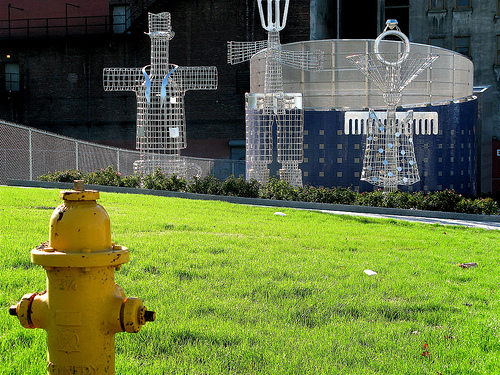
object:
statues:
[222, 0, 324, 198]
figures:
[103, 11, 221, 190]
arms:
[101, 65, 150, 92]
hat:
[144, 11, 177, 41]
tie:
[142, 63, 178, 108]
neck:
[142, 59, 179, 72]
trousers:
[245, 92, 303, 167]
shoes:
[245, 166, 271, 196]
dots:
[394, 132, 401, 138]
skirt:
[358, 103, 422, 187]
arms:
[344, 50, 439, 104]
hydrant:
[8, 180, 154, 375]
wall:
[227, 0, 500, 195]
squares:
[302, 121, 479, 194]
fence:
[0, 116, 245, 189]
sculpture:
[105, 11, 218, 182]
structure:
[228, 0, 322, 193]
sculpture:
[344, 16, 439, 200]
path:
[6, 174, 498, 229]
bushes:
[261, 175, 299, 201]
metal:
[244, 39, 480, 196]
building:
[233, 0, 500, 198]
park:
[0, 0, 500, 373]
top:
[144, 11, 177, 42]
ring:
[373, 19, 410, 68]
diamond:
[385, 18, 397, 30]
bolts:
[9, 308, 19, 316]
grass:
[2, 182, 499, 375]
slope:
[0, 188, 500, 375]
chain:
[0, 122, 246, 186]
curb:
[1, 179, 500, 227]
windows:
[336, 0, 380, 41]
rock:
[458, 262, 479, 269]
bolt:
[145, 310, 155, 321]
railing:
[0, 11, 166, 51]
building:
[0, 0, 251, 180]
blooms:
[482, 198, 485, 202]